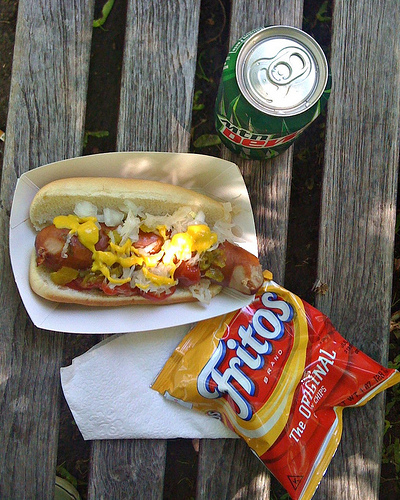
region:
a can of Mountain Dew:
[213, 23, 330, 162]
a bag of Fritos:
[149, 270, 397, 498]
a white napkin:
[58, 323, 238, 444]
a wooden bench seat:
[2, 0, 398, 499]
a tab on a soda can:
[267, 49, 307, 84]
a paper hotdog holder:
[7, 149, 260, 345]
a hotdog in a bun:
[34, 223, 264, 291]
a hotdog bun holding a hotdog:
[28, 175, 229, 309]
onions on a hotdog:
[74, 202, 197, 234]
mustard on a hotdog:
[53, 213, 99, 252]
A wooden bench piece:
[135, 30, 175, 135]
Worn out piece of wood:
[27, 39, 71, 102]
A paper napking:
[95, 374, 145, 430]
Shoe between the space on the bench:
[57, 486, 72, 499]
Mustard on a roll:
[82, 228, 94, 239]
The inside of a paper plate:
[86, 161, 115, 173]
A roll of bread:
[76, 183, 158, 197]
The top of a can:
[260, 41, 309, 100]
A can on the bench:
[234, 102, 286, 150]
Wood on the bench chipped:
[317, 285, 326, 291]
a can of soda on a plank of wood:
[214, 23, 328, 157]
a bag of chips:
[150, 268, 396, 497]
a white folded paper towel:
[59, 323, 240, 439]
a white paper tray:
[11, 151, 261, 332]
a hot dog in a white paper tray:
[28, 177, 264, 306]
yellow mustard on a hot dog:
[54, 212, 219, 290]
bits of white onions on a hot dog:
[62, 201, 238, 309]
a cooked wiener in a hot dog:
[36, 222, 265, 294]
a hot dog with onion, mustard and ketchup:
[30, 177, 267, 302]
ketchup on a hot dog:
[66, 237, 199, 301]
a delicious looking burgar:
[45, 178, 222, 285]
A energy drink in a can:
[218, 45, 327, 144]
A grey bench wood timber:
[317, 125, 398, 333]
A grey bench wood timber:
[205, 445, 261, 495]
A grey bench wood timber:
[93, 449, 186, 498]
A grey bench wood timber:
[4, 365, 49, 457]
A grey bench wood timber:
[122, 12, 203, 125]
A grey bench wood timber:
[9, 28, 71, 150]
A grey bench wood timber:
[326, 451, 386, 499]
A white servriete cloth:
[46, 348, 186, 425]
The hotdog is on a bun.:
[6, 141, 272, 343]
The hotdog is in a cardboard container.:
[3, 136, 274, 344]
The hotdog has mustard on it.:
[8, 144, 276, 335]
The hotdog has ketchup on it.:
[5, 138, 281, 339]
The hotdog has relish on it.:
[7, 141, 279, 343]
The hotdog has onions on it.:
[5, 143, 265, 332]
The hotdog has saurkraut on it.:
[6, 141, 278, 337]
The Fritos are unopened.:
[147, 267, 399, 497]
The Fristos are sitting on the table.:
[114, 268, 392, 497]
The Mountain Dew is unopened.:
[194, 19, 346, 166]